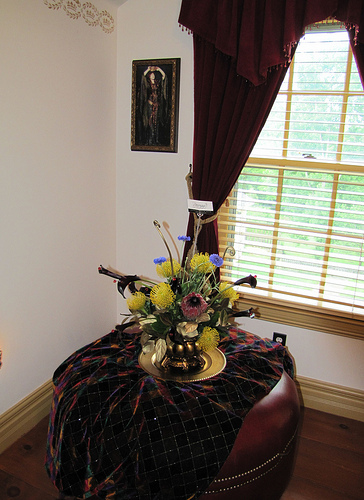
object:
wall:
[0, 0, 364, 408]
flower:
[149, 281, 177, 309]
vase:
[161, 322, 206, 374]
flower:
[180, 291, 209, 323]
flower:
[209, 253, 225, 268]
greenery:
[213, 290, 229, 324]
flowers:
[217, 281, 241, 308]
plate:
[136, 333, 227, 385]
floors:
[0, 403, 363, 499]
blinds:
[211, 8, 364, 313]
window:
[183, 0, 364, 341]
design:
[39, 0, 120, 36]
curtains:
[174, 0, 364, 311]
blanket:
[37, 315, 300, 500]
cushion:
[45, 326, 304, 499]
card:
[186, 197, 214, 213]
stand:
[175, 195, 221, 296]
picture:
[128, 55, 182, 155]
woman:
[138, 63, 171, 147]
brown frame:
[129, 57, 183, 153]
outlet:
[272, 330, 287, 347]